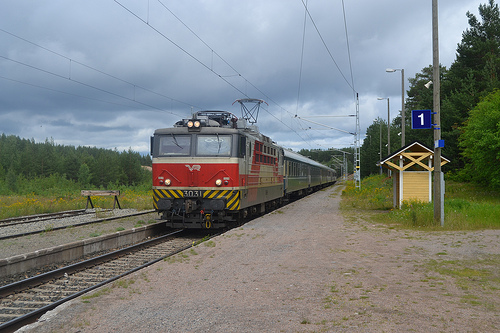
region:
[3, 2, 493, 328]
the photo was taken outside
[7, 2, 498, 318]
the photo is clear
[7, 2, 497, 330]
the photo was taken during the day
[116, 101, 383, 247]
a train is in the photo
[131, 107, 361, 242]
the train is red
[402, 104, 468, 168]
number 1 is written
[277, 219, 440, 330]
the ground is bare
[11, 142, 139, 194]
trees are in the photo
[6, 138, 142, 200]
the trees are green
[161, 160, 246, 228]
train lights are on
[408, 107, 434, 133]
A square sign hanging from the light pole is blue.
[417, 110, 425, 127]
The blue sign has a white number 1 painted on it.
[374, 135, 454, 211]
A small structure painted yellow and shaped like a small house is on the other side of the light post with the blue sign hanging on it.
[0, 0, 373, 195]
Long cables are above the tracks.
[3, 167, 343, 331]
The cable car is on tracks.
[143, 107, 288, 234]
The engine of the cable car is red.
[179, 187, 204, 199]
The number 3031 is painted on the front of the red engine.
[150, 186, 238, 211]
The front bottom panel on the red engine is striped.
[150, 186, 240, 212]
The stripes on the panel are black and yellow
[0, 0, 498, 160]
The sky is cloudy and stormy looking.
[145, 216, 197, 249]
a shadow is cast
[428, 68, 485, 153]
the plants are green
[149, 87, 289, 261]
the train headlights are on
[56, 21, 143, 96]
the clouds are grey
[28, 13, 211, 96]
the sky is covered by clouds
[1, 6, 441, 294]
it is cloudy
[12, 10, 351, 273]
it is in a railway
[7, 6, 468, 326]
it is a daytime scene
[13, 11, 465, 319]
it is an outdoor scene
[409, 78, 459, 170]
the 1 sign is blue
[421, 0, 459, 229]
tall wooden pole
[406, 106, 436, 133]
small square blue sign with white number 1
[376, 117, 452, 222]
small yellow building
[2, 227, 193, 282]
train tracks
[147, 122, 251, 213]
front of red and yellow train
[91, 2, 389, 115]
wires above the train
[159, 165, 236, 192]
headlight on front of train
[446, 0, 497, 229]
Green trees and grass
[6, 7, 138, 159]
clouds in the sky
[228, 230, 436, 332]
dirt and gravel on the ground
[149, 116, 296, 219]
this is a train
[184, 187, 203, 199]
this is the train's number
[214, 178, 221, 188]
this is the train's headlight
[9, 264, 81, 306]
part of the rail tracks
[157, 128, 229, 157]
this is the train's windows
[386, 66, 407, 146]
this is a lamp post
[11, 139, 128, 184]
this is the area's vegetation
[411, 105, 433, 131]
this is a signpost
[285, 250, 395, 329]
this is part of the ground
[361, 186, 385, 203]
this is part of the grass